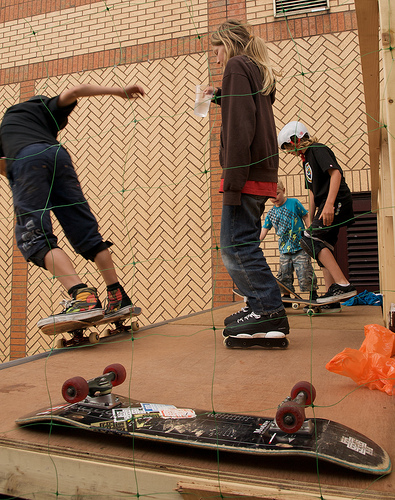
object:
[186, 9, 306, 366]
girl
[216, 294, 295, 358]
skates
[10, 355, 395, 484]
skateboard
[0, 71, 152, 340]
boy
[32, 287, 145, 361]
skateboard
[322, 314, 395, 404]
paper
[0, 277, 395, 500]
ground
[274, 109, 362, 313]
boy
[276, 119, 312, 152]
helmet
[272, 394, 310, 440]
wheels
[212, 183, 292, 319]
jeans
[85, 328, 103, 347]
wheels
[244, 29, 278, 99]
ponytail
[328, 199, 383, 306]
ramp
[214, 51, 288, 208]
jacket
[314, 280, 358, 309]
sneakers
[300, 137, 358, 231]
shirt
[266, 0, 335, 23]
vent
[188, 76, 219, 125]
cup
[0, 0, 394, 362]
wall